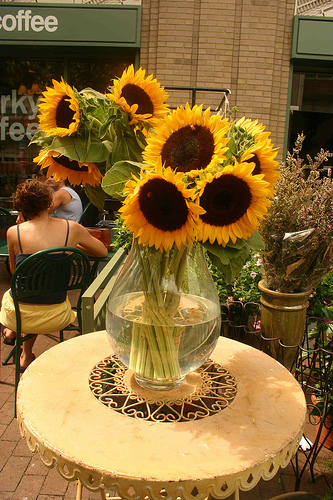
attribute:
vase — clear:
[104, 235, 219, 391]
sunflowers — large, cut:
[81, 101, 283, 239]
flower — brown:
[300, 206, 312, 215]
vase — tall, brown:
[256, 280, 308, 377]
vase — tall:
[258, 279, 312, 368]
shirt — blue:
[54, 185, 85, 221]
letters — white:
[0, 7, 68, 37]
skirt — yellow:
[0, 287, 76, 332]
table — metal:
[19, 317, 299, 496]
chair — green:
[3, 243, 88, 364]